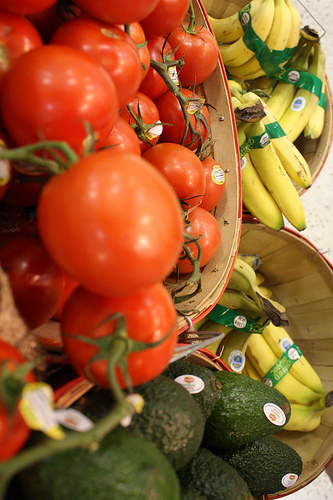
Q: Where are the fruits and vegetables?
A: In baskets.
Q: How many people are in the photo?
A: None.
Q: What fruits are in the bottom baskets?
A: Bananas.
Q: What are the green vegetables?
A: Avocados.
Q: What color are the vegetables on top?
A: Red.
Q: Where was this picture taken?
A: Outside of a store.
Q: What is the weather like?
A: Bright and sunny.